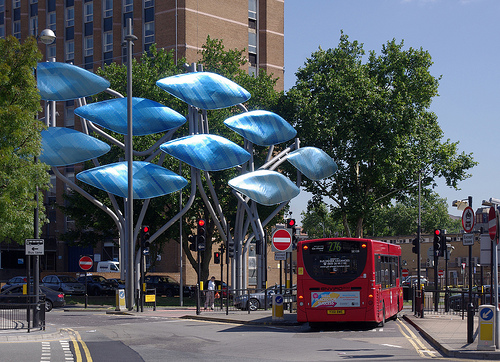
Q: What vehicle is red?
A: Bus.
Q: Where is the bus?
A: On the street.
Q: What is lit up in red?
A: The traffic lights.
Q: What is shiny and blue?
A: The sculpture.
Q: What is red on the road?
A: The bus.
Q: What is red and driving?
A: The bus.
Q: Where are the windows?
A: On the building.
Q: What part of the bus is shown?
A: The back.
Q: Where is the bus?
A: On the street.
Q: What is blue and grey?
A: The sculpture.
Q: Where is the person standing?
A: On the street corner.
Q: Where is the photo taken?
A: City street.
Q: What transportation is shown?
A: A bus.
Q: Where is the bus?
A: Stopped at stop light.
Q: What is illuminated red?
A: Traffic signal.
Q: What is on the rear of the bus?
A: Advertising.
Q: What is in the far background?
A: Brick building.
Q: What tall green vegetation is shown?
A: A tree.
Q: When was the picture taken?
A: During the day.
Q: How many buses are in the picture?
A: One.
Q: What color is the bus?
A: Red.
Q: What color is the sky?
A: Blue.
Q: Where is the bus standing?
A: At a traffic sign.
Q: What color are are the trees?
A: Green.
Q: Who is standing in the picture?
A: A man.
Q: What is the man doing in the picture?
A: Standing.